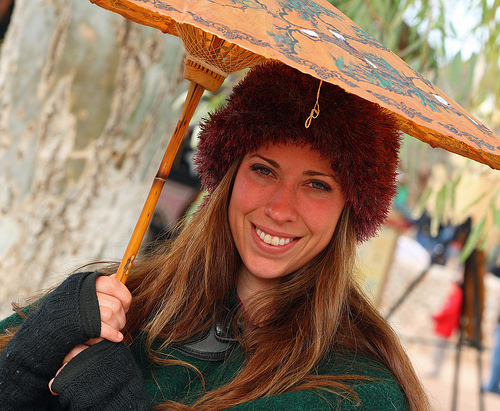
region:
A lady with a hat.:
[0, 61, 435, 409]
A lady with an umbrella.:
[2, 0, 497, 408]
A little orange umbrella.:
[88, 1, 498, 283]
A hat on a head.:
[193, 60, 398, 245]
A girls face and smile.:
[230, 139, 344, 279]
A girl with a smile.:
[3, 60, 430, 410]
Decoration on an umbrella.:
[196, 25, 498, 170]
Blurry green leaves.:
[331, 1, 498, 265]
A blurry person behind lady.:
[426, 273, 466, 379]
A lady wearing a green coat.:
[2, 60, 429, 408]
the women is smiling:
[249, 224, 296, 248]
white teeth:
[255, 229, 290, 247]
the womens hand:
[89, 265, 132, 355]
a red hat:
[244, 75, 281, 117]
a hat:
[340, 112, 379, 181]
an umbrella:
[289, 5, 384, 87]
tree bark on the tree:
[46, 8, 133, 213]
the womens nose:
[267, 185, 297, 221]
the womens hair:
[257, 308, 326, 370]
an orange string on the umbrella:
[305, 76, 322, 133]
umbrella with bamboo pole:
[96, 1, 497, 279]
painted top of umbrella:
[251, 0, 443, 99]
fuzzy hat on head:
[197, 59, 397, 280]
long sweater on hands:
[1, 270, 132, 409]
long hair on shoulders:
[130, 179, 419, 406]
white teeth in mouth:
[250, 224, 295, 248]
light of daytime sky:
[407, 1, 499, 57]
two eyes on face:
[248, 160, 328, 193]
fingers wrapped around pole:
[100, 275, 132, 343]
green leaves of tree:
[367, 2, 494, 67]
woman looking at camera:
[189, 88, 428, 300]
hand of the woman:
[35, 244, 162, 371]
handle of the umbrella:
[74, 89, 229, 261]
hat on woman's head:
[196, 94, 400, 178]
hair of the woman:
[273, 268, 369, 352]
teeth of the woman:
[253, 219, 291, 251]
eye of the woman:
[241, 155, 286, 194]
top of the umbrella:
[281, 15, 388, 64]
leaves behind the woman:
[398, 10, 489, 49]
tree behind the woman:
[21, 61, 143, 158]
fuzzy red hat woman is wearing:
[193, 70, 403, 223]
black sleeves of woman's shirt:
[11, 272, 132, 409]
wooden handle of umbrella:
[107, 77, 219, 287]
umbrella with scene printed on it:
[117, 2, 499, 147]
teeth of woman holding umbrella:
[255, 229, 290, 248]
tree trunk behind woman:
[5, 3, 207, 289]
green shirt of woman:
[137, 293, 407, 408]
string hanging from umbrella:
[300, 83, 325, 127]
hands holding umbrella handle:
[18, 275, 142, 397]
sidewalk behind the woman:
[376, 227, 493, 409]